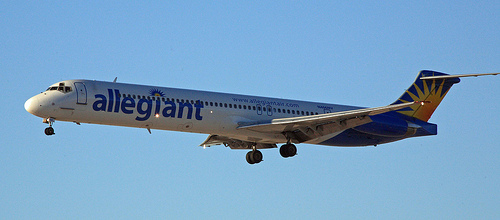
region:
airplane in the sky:
[19, 44, 475, 175]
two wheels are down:
[232, 136, 303, 168]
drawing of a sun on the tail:
[383, 71, 457, 123]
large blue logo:
[88, 78, 215, 132]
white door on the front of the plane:
[69, 78, 94, 109]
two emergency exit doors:
[254, 100, 276, 118]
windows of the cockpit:
[36, 78, 73, 99]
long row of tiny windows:
[120, 87, 325, 119]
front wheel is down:
[36, 120, 59, 138]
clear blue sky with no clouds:
[2, 2, 492, 215]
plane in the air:
[0, 15, 492, 204]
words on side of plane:
[71, 91, 218, 136]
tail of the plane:
[378, 56, 471, 133]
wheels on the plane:
[219, 134, 309, 184]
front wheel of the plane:
[21, 113, 75, 154]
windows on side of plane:
[203, 97, 254, 127]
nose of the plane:
[1, 83, 56, 139]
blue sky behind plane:
[111, 12, 224, 74]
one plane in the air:
[4, 40, 467, 182]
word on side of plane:
[85, 86, 209, 138]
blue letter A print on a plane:
[88, 91, 106, 114]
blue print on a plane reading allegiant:
[93, 85, 211, 117]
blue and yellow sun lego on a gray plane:
[146, 85, 168, 97]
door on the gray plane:
[72, 81, 88, 105]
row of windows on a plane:
[101, 90, 323, 115]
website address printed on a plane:
[227, 94, 305, 108]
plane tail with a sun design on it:
[389, 68, 461, 120]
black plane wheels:
[241, 150, 266, 162]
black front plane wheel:
[44, 118, 57, 135]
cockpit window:
[43, 83, 74, 95]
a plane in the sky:
[21, 62, 498, 172]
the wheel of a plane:
[43, 122, 62, 139]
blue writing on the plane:
[87, 84, 207, 129]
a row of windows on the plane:
[115, 90, 324, 118]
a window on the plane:
[129, 92, 138, 100]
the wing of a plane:
[235, 93, 440, 148]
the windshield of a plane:
[41, 83, 77, 96]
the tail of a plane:
[385, 64, 499, 128]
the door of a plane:
[71, 77, 90, 108]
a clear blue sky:
[0, 0, 497, 219]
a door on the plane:
[70, 77, 90, 106]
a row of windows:
[115, 88, 327, 123]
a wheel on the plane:
[41, 120, 60, 140]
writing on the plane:
[87, 82, 212, 129]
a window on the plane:
[120, 90, 128, 100]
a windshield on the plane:
[43, 83, 76, 97]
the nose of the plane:
[19, 87, 46, 121]